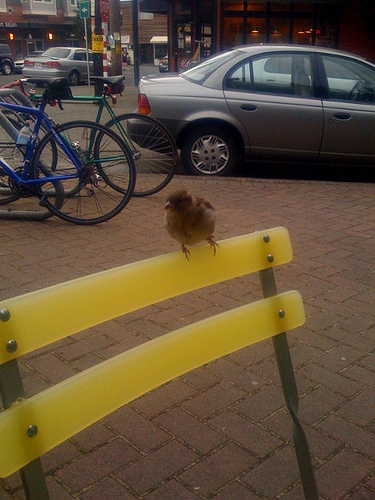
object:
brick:
[178, 382, 241, 415]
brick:
[211, 409, 282, 454]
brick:
[115, 436, 202, 494]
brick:
[181, 439, 254, 493]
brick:
[150, 400, 228, 454]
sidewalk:
[292, 185, 374, 243]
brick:
[75, 474, 135, 500]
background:
[128, 7, 215, 44]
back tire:
[180, 122, 240, 177]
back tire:
[67, 69, 82, 88]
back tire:
[1, 61, 13, 75]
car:
[124, 41, 373, 181]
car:
[0, 40, 18, 76]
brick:
[293, 201, 336, 227]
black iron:
[268, 339, 319, 499]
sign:
[91, 34, 103, 53]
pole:
[92, 0, 103, 97]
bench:
[0, 225, 319, 499]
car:
[20, 43, 110, 86]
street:
[5, 64, 127, 160]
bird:
[161, 188, 219, 261]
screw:
[1, 310, 10, 320]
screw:
[4, 340, 17, 350]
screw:
[262, 233, 271, 243]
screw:
[266, 252, 274, 262]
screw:
[276, 306, 285, 317]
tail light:
[135, 85, 153, 118]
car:
[155, 50, 174, 74]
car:
[13, 50, 46, 73]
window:
[223, 50, 319, 95]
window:
[324, 52, 374, 107]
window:
[186, 52, 236, 79]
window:
[43, 47, 70, 57]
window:
[73, 49, 89, 63]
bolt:
[27, 423, 38, 436]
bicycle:
[0, 77, 135, 224]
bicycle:
[6, 75, 177, 197]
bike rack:
[0, 87, 62, 221]